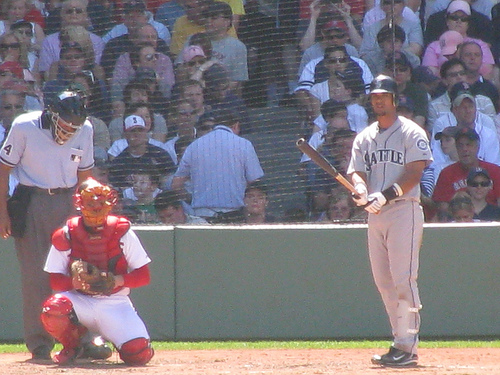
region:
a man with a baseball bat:
[286, 57, 481, 371]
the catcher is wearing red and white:
[26, 172, 191, 369]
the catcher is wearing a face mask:
[68, 168, 128, 237]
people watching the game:
[0, 1, 499, 256]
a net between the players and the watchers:
[2, 1, 499, 225]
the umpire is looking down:
[0, 68, 155, 364]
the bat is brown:
[278, 117, 394, 219]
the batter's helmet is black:
[351, 69, 416, 124]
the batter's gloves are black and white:
[324, 174, 426, 222]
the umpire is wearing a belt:
[6, 82, 108, 327]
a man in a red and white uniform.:
[44, 174, 155, 368]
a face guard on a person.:
[64, 162, 120, 250]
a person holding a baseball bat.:
[289, 134, 381, 216]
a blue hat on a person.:
[364, 66, 404, 108]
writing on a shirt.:
[352, 140, 407, 184]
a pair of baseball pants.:
[361, 185, 431, 352]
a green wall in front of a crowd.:
[0, 216, 499, 348]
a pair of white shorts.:
[66, 290, 153, 348]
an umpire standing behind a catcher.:
[1, 82, 103, 365]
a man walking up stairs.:
[167, 107, 265, 228]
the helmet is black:
[309, 26, 418, 140]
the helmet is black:
[334, 50, 409, 179]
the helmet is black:
[329, 59, 447, 216]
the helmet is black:
[313, 28, 498, 318]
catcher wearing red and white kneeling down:
[0, 165, 167, 372]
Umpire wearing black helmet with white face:
[33, 86, 95, 166]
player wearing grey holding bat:
[280, 45, 452, 371]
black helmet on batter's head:
[358, 72, 402, 114]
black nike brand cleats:
[371, 340, 438, 373]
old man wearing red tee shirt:
[435, 124, 499, 199]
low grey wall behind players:
[172, 225, 392, 347]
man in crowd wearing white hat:
[118, 109, 168, 173]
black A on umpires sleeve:
[1, 141, 20, 164]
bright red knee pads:
[36, 295, 175, 373]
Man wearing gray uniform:
[327, 74, 437, 366]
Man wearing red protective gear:
[44, 170, 157, 373]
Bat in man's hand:
[288, 129, 385, 219]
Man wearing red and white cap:
[109, 113, 181, 185]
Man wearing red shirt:
[423, 129, 499, 205]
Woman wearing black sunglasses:
[461, 166, 496, 219]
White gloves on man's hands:
[349, 171, 398, 228]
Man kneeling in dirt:
[25, 180, 168, 370]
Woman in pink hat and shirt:
[425, 4, 493, 84]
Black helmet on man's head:
[357, 66, 431, 136]